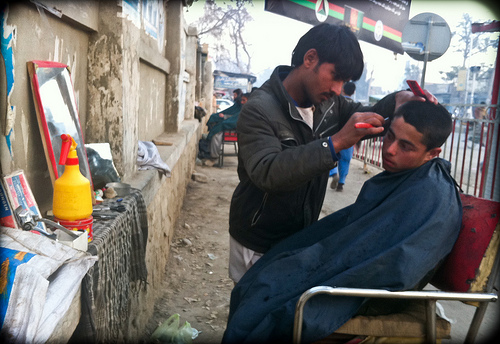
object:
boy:
[231, 99, 468, 340]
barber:
[207, 19, 436, 281]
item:
[354, 114, 392, 132]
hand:
[336, 109, 383, 147]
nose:
[330, 77, 345, 96]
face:
[298, 60, 353, 103]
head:
[381, 99, 454, 174]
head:
[288, 20, 363, 104]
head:
[240, 92, 250, 104]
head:
[232, 88, 243, 99]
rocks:
[179, 238, 194, 248]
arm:
[292, 285, 496, 342]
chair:
[291, 188, 498, 341]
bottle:
[46, 134, 96, 245]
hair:
[392, 101, 453, 149]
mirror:
[31, 59, 96, 205]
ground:
[162, 149, 237, 336]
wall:
[4, 3, 212, 340]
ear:
[425, 147, 441, 160]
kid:
[203, 93, 249, 169]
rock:
[183, 237, 191, 248]